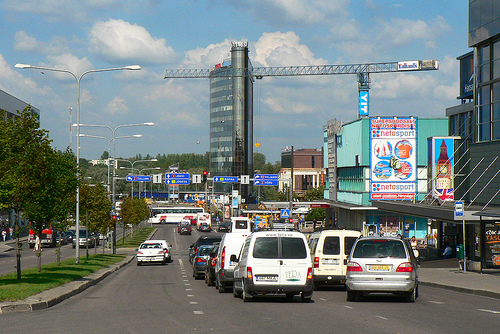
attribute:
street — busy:
[2, 221, 499, 334]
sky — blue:
[0, 1, 470, 163]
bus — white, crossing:
[148, 205, 204, 223]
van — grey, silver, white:
[348, 237, 421, 302]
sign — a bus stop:
[456, 199, 468, 272]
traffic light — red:
[202, 170, 211, 185]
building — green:
[323, 116, 450, 264]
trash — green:
[456, 243, 466, 260]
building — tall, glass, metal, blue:
[205, 42, 253, 205]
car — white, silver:
[138, 241, 167, 265]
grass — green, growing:
[1, 254, 128, 302]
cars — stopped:
[136, 229, 417, 303]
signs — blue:
[124, 172, 280, 187]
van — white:
[231, 230, 313, 300]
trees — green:
[1, 102, 155, 280]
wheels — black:
[345, 286, 418, 304]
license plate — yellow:
[370, 264, 393, 272]